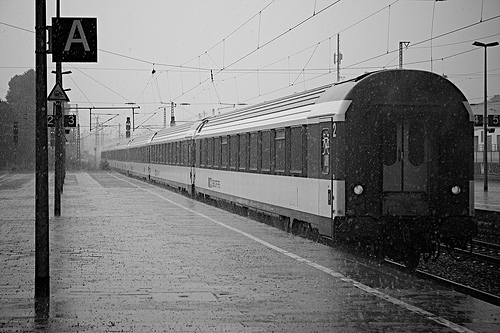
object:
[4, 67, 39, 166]
trees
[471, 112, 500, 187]
building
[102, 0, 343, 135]
wires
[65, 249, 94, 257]
bricks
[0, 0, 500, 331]
rain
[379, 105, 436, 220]
doors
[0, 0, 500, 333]
photo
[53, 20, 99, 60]
letter a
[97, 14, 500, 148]
wiring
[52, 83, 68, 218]
pole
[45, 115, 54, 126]
numer 2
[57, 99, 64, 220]
pole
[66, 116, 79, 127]
number 3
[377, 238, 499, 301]
train tracks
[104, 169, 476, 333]
line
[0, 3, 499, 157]
sky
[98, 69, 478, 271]
train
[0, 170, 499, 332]
platform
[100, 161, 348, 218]
stripe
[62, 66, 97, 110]
lines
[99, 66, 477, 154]
train roof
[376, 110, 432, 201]
doors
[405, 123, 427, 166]
windows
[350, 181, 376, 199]
light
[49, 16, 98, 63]
sign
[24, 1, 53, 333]
post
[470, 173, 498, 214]
platform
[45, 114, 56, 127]
sign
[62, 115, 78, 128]
sign